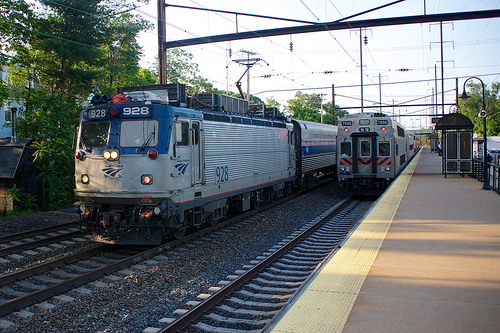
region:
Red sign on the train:
[107, 86, 132, 103]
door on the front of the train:
[350, 133, 374, 187]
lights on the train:
[76, 168, 156, 188]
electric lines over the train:
[147, 2, 432, 111]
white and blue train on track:
[76, 95, 337, 238]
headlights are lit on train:
[73, 161, 160, 188]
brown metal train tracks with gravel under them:
[16, 184, 363, 324]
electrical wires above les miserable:
[0, 5, 499, 137]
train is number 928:
[122, 101, 151, 118]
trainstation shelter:
[430, 105, 475, 171]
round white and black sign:
[476, 108, 491, 114]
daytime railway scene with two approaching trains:
[3, 18, 497, 327]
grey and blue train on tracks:
[66, 75, 337, 245]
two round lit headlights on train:
[75, 163, 155, 190]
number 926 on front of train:
[123, 100, 152, 119]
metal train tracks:
[1, 182, 376, 328]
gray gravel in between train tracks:
[5, 182, 373, 323]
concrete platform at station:
[286, 148, 499, 330]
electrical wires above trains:
[151, 0, 497, 156]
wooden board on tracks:
[197, 292, 281, 310]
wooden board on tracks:
[241, 260, 307, 283]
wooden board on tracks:
[13, 276, 79, 303]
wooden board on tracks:
[1, 283, 57, 312]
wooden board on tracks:
[36, 273, 93, 294]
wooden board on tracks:
[55, 267, 107, 290]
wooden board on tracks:
[69, 263, 122, 281]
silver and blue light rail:
[67, 91, 322, 210]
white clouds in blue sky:
[193, 35, 216, 52]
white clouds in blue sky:
[240, 42, 266, 82]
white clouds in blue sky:
[322, 29, 349, 61]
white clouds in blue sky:
[282, 59, 317, 88]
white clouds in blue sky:
[405, 29, 425, 49]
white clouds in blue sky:
[364, 22, 391, 64]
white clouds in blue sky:
[462, 33, 479, 63]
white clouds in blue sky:
[317, 31, 364, 73]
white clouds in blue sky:
[379, 44, 403, 81]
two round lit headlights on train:
[74, 160, 160, 191]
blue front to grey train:
[81, 92, 203, 162]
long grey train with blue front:
[66, 95, 339, 250]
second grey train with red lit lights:
[333, 110, 425, 197]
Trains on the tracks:
[103, 76, 383, 220]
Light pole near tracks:
[455, 70, 497, 195]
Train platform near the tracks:
[384, 137, 487, 332]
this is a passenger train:
[81, 103, 281, 251]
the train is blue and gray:
[74, 118, 214, 242]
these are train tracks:
[43, 241, 113, 327]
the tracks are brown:
[13, 220, 96, 304]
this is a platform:
[292, 220, 412, 319]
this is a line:
[344, 203, 425, 285]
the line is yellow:
[327, 178, 425, 330]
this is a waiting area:
[414, 94, 495, 184]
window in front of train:
[79, 120, 119, 143]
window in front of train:
[119, 118, 160, 147]